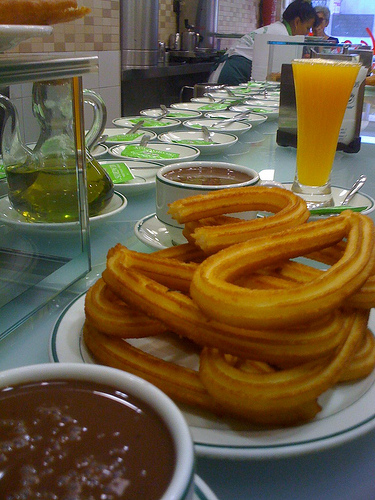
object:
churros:
[82, 185, 375, 430]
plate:
[47, 261, 374, 462]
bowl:
[0, 363, 195, 498]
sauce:
[0, 376, 177, 500]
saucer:
[194, 471, 217, 500]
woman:
[207, 0, 319, 86]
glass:
[290, 59, 360, 211]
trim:
[188, 421, 375, 463]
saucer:
[258, 182, 375, 219]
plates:
[157, 130, 239, 156]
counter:
[0, 81, 374, 500]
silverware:
[202, 126, 213, 143]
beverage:
[290, 59, 362, 210]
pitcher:
[0, 78, 113, 223]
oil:
[6, 154, 115, 224]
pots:
[180, 19, 204, 52]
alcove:
[122, 0, 224, 110]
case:
[0, 53, 100, 346]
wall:
[0, 1, 121, 147]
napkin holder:
[276, 64, 367, 153]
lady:
[312, 6, 339, 43]